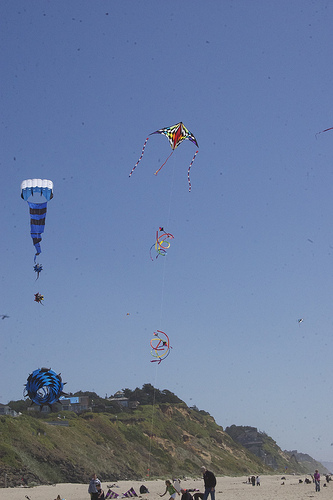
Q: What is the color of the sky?
A: Blue.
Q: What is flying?
A: Kites.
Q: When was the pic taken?
A: During the day.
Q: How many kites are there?
A: 5.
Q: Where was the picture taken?
A: At the beach.